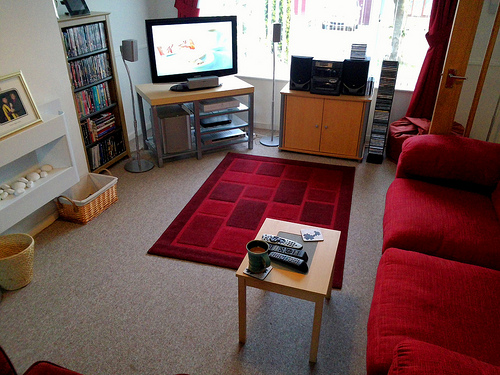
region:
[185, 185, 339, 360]
Small wooden tablle with cluter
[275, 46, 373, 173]
Small wooden tablle with cluter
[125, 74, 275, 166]
Small wooden tablle with cluter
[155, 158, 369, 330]
Small red rug on floor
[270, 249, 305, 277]
Black remote sitting on table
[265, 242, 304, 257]
Black remote sitting on table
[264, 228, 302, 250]
Black remote sitting on table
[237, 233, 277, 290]
Cup of coffee sitting on table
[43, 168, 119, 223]
Small brown and white basket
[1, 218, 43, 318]
Small brown basket on floor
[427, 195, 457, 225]
the couch is red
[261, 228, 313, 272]
the remotes are on the table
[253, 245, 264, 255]
the liquid is brown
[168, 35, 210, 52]
the tv is on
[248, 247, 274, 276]
the cup is on the coaster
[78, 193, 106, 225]
the basket is on the floor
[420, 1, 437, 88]
the curtain is pulled back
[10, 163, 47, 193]
the rocks are on the shelf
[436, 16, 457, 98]
the door is open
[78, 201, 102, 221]
the basket is wicker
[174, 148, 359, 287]
A red rug on the grey carpet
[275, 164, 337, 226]
Rectangular red patterns on the rug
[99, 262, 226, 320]
A grey carpet beneath the red rug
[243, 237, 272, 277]
A green mug of coffee on the table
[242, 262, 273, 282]
A small coaster beneath the mug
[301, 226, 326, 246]
A white and blue coaster on the table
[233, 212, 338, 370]
A small wooden table by the couch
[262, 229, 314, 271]
Three remote controls on the table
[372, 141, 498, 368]
A large red couch by the wooden table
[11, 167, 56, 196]
A number of small white rocks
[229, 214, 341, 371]
light brown coffee table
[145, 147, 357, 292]
red rectangle carpet on the floor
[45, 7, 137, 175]
brown wooden bookcase against the wall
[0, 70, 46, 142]
picture in gold frame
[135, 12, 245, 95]
black lcd television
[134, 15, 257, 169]
television on brown tv stand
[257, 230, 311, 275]
three remotes on the coffee table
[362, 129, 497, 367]
red couch with cushions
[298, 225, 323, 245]
white coaster on the coffee table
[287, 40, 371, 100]
black stereo music system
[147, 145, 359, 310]
a red decorative rug is over the carpet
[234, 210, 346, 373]
a wooden table is in front of the red sofa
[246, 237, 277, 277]
a mug of coffee is on the table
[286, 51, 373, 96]
a music system is on a cabinet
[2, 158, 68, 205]
rocks are on a white shelf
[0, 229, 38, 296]
a round wicker basket is on the floor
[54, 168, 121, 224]
a rectangle wicker basket has handles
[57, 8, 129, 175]
a tall shelf is full of books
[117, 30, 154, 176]
a floor lamp is in the living room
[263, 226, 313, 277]
remote controls are on the table